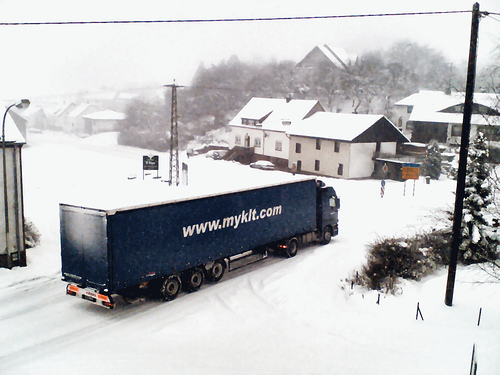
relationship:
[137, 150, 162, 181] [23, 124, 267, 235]
sign on ground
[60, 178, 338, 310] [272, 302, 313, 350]
truck driving in snow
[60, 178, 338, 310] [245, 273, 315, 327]
truck driving in snow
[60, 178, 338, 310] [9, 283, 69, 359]
truck leaving behind snow tracks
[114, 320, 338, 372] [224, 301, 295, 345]
ground s covered in snow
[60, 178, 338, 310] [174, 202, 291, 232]
truck has white words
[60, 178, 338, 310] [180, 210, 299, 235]
truck has has website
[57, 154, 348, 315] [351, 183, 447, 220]
truck driving in snow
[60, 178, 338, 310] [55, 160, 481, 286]
truck driving in snow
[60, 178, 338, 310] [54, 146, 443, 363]
truck driving in snow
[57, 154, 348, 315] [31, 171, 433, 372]
truck driving in snow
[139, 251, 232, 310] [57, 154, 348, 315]
wheels of a truck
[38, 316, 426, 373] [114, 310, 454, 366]
snow on ground